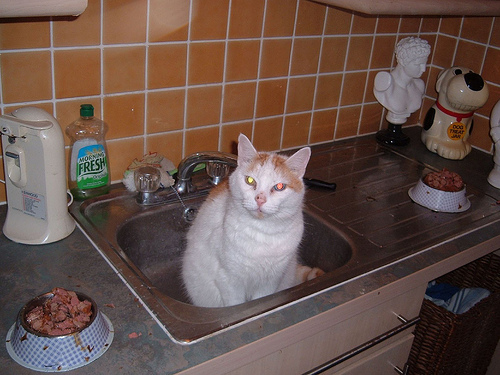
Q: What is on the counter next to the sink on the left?
A: A bowl of food.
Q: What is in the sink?
A: A cat.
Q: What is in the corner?
A: A statue.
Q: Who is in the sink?
A: A white cat.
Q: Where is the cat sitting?
A: In the sink.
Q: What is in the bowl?
A: Animal food.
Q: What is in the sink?
A: A cat.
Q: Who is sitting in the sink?
A: A cat.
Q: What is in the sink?
A: A cat.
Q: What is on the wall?
A: Brown ceramic tiles.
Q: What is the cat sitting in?
A: The sink.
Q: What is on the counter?
A: Electric can opener.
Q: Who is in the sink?
A: The cat.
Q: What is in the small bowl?
A: Cat food.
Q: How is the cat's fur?
A: Orange and white.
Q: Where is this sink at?
A: In the kitchen.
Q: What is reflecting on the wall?
A: Light.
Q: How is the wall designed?
A: With tiles.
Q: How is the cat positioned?
A: Sitting.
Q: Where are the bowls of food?
A: On either side of the sink.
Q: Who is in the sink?
A: A cat.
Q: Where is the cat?
A: In the sink.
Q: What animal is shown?
A: A cat.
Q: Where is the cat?
A: In the sink.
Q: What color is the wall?
A: Orange.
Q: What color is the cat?
A: White and orange.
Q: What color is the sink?
A: Silver.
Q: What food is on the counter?
A: Cat food.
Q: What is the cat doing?
A: Sitting in the sink.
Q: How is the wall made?
A: Of tile.